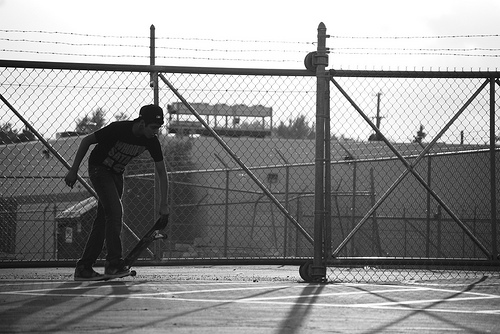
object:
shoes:
[101, 259, 132, 279]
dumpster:
[52, 195, 97, 261]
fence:
[120, 146, 499, 259]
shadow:
[0, 272, 497, 331]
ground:
[0, 257, 496, 333]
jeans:
[76, 160, 123, 266]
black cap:
[132, 104, 164, 120]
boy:
[62, 102, 174, 284]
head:
[138, 104, 164, 140]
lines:
[333, 281, 500, 301]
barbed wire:
[0, 27, 318, 48]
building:
[1, 132, 498, 260]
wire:
[323, 32, 500, 39]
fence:
[2, 23, 498, 288]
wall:
[190, 137, 500, 262]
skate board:
[114, 213, 168, 275]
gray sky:
[3, 3, 498, 144]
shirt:
[88, 120, 164, 171]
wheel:
[299, 260, 314, 283]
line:
[365, 295, 495, 306]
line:
[241, 288, 423, 301]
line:
[116, 284, 348, 296]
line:
[20, 282, 260, 292]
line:
[1, 292, 499, 316]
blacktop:
[2, 267, 499, 333]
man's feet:
[74, 264, 106, 281]